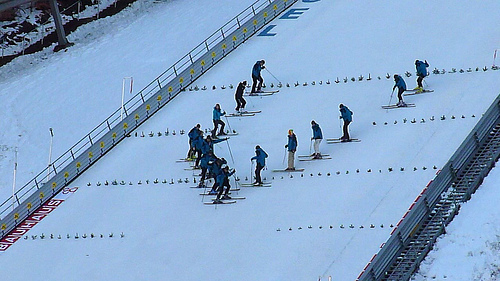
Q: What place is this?
A: It is a path.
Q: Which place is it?
A: It is a path.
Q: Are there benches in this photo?
A: No, there are no benches.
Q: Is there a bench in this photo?
A: No, there are no benches.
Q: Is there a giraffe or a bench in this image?
A: No, there are no benches or giraffes.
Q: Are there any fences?
A: Yes, there is a fence.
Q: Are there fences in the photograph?
A: Yes, there is a fence.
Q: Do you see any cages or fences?
A: Yes, there is a fence.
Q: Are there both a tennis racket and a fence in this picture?
A: No, there is a fence but no rackets.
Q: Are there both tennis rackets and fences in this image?
A: No, there is a fence but no rackets.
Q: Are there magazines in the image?
A: No, there are no magazines.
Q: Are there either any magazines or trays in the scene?
A: No, there are no magazines or trays.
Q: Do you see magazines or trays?
A: No, there are no magazines or trays.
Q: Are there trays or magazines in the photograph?
A: No, there are no magazines or trays.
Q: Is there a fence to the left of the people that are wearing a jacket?
A: Yes, there is a fence to the left of the people.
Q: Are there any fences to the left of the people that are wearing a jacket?
A: Yes, there is a fence to the left of the people.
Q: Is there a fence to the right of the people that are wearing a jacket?
A: No, the fence is to the left of the people.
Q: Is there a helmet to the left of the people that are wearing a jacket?
A: No, there is a fence to the left of the people.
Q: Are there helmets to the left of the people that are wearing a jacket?
A: No, there is a fence to the left of the people.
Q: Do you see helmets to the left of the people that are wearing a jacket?
A: No, there is a fence to the left of the people.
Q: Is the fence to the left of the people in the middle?
A: Yes, the fence is to the left of the people.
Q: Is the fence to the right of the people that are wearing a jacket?
A: No, the fence is to the left of the people.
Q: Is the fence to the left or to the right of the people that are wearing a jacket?
A: The fence is to the left of the people.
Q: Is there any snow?
A: Yes, there is snow.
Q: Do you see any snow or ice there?
A: Yes, there is snow.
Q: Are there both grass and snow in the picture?
A: No, there is snow but no grass.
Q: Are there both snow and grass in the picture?
A: No, there is snow but no grass.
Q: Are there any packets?
A: No, there are no packets.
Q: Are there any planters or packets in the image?
A: No, there are no packets or planters.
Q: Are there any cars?
A: No, there are no cars.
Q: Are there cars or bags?
A: No, there are no cars or bags.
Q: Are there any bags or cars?
A: No, there are no cars or bags.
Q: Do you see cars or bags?
A: No, there are no cars or bags.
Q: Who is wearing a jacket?
A: The people are wearing a jacket.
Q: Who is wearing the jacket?
A: The people are wearing a jacket.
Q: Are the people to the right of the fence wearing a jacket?
A: Yes, the people are wearing a jacket.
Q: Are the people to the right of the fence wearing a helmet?
A: No, the people are wearing a jacket.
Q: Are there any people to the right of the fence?
A: Yes, there are people to the right of the fence.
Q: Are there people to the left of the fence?
A: No, the people are to the right of the fence.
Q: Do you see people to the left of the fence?
A: No, the people are to the right of the fence.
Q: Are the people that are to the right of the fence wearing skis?
A: Yes, the people are wearing skis.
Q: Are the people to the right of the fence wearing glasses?
A: No, the people are wearing skis.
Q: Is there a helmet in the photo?
A: No, there are no helmets.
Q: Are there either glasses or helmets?
A: No, there are no helmets or glasses.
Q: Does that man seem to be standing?
A: Yes, the man is standing.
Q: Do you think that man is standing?
A: Yes, the man is standing.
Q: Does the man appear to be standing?
A: Yes, the man is standing.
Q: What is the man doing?
A: The man is standing.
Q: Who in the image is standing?
A: The man is standing.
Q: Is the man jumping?
A: No, the man is standing.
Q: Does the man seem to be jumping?
A: No, the man is standing.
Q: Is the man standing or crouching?
A: The man is standing.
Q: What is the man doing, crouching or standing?
A: The man is standing.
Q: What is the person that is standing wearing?
A: The man is wearing skis.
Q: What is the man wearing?
A: The man is wearing skis.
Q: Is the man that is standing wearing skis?
A: Yes, the man is wearing skis.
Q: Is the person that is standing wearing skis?
A: Yes, the man is wearing skis.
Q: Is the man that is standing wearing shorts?
A: No, the man is wearing skis.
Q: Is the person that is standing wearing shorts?
A: No, the man is wearing skis.